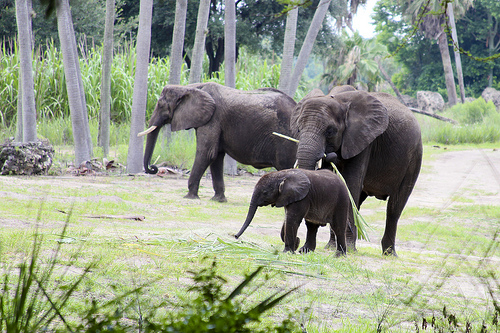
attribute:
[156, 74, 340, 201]
elephant — grey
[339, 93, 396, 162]
ear — gray, large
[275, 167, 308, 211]
ear — gray, large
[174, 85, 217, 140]
ear — gray, large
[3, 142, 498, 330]
ground — flat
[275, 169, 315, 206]
ear — large, gray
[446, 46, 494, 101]
tree — tall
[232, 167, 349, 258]
elephant — baby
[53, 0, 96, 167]
tree — tall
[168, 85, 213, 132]
ear — large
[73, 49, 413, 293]
field — green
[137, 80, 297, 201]
elephant — grey, gray, adult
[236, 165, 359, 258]
elephant — baby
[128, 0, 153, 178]
tree stem — tall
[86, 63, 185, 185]
stem — tall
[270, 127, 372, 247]
stalk — long, curved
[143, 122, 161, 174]
trunk — curled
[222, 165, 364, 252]
elephant — gray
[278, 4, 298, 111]
tree stem — tall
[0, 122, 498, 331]
leaves — spiky, oval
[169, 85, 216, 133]
ear — gray, large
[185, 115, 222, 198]
leg — large, gray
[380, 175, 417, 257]
leg — large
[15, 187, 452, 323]
field — grassy